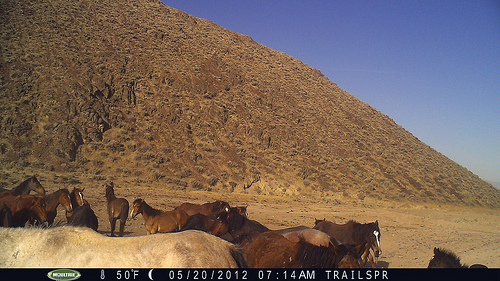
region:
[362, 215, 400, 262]
head of a horse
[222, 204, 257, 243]
head of a horse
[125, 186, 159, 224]
head of a horse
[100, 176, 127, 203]
head of a horse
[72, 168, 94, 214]
head of a horse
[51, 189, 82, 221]
head of a horse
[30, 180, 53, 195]
head of a horse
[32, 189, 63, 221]
head of a horse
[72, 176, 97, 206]
a head of a horse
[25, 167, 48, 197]
a head of a horse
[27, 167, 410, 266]
large group of horses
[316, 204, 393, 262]
brown and white horse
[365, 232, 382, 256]
white stripe on horse's face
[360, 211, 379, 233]
horse has brown ears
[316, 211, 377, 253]
horse has brown hide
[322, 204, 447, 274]
ground is light brown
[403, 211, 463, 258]
brown and dry desert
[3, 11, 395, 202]
tall and brown hill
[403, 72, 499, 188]
blue and white sky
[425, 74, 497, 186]
thin clouds near horizon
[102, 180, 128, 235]
a brown horse in desert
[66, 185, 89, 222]
a brown horse in desert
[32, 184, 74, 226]
a brown horse in desert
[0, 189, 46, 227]
a brown horse in desert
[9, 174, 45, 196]
a brown horse in desert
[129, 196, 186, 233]
a brown horse in desert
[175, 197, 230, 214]
a brown horse in desert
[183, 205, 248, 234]
a brown horse in desert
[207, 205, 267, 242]
a brown horse in desert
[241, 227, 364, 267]
a brown horse in desert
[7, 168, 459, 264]
a large herd of horses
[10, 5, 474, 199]
the base of a large mountain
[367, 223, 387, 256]
a white stripe on a horse's nose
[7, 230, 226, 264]
the back of a grayish white horse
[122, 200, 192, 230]
a golden brown horse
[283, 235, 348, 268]
a horse's nearly black mane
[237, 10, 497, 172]
a patch of clear blue sky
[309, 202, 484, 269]
a patch of bare dirt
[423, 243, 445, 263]
a horse's ears pricked straight up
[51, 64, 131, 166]
a rocky outcrop on a hillside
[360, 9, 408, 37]
white clouds in blue sky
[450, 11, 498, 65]
white clouds in blue sky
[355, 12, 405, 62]
white clouds in blue sky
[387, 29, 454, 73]
white clouds in blue sky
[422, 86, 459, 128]
white clouds in blue sky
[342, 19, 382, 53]
white clouds in blue sky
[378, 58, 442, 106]
white clouds in blue sky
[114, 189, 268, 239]
brown cow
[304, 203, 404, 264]
cow